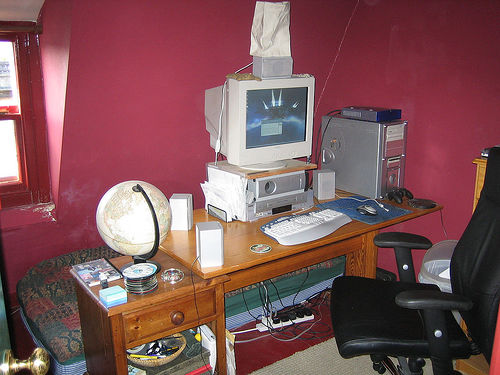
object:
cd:
[246, 241, 272, 255]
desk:
[154, 180, 444, 375]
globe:
[94, 177, 174, 255]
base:
[131, 259, 146, 266]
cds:
[120, 261, 164, 297]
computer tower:
[317, 113, 410, 201]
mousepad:
[316, 192, 414, 227]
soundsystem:
[203, 162, 309, 200]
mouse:
[354, 203, 382, 218]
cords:
[240, 286, 335, 341]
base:
[239, 160, 288, 173]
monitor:
[243, 86, 307, 150]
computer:
[202, 75, 316, 172]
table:
[66, 248, 234, 374]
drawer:
[120, 284, 218, 350]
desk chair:
[326, 145, 500, 374]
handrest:
[391, 287, 473, 312]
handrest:
[370, 230, 436, 252]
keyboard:
[256, 206, 354, 248]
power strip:
[252, 309, 316, 333]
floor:
[222, 286, 457, 374]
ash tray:
[159, 266, 184, 285]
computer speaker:
[250, 55, 295, 82]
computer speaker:
[193, 219, 225, 270]